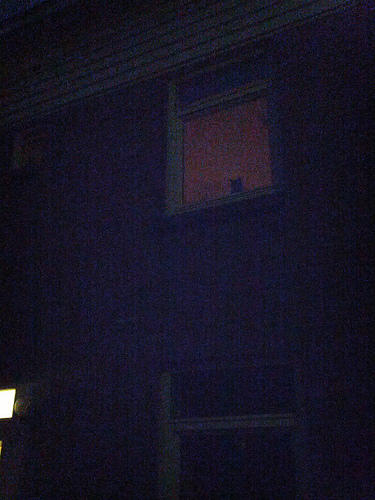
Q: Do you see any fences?
A: No, there are no fences.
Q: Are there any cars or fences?
A: No, there are no fences or cars.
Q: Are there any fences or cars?
A: No, there are no fences or cars.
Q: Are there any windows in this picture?
A: Yes, there is a window.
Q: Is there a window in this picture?
A: Yes, there is a window.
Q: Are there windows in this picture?
A: Yes, there is a window.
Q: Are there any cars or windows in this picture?
A: Yes, there is a window.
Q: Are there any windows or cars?
A: Yes, there is a window.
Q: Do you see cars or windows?
A: Yes, there is a window.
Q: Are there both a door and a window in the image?
A: Yes, there are both a window and a door.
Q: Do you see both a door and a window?
A: Yes, there are both a window and a door.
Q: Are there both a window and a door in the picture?
A: Yes, there are both a window and a door.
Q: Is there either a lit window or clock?
A: Yes, there is a lit window.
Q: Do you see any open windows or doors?
A: Yes, there is an open window.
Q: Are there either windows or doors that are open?
A: Yes, the window is open.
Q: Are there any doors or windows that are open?
A: Yes, the window is open.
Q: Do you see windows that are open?
A: Yes, there is an open window.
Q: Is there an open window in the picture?
A: Yes, there is an open window.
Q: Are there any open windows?
A: Yes, there is an open window.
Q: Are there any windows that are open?
A: Yes, there is a window that is open.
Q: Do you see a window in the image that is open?
A: Yes, there is a window that is open.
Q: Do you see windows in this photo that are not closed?
A: Yes, there is a open window.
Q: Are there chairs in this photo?
A: No, there are no chairs.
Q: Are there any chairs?
A: No, there are no chairs.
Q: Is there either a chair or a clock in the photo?
A: No, there are no chairs or clocks.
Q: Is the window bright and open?
A: Yes, the window is bright and open.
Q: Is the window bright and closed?
A: No, the window is bright but open.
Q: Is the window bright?
A: Yes, the window is bright.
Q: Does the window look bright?
A: Yes, the window is bright.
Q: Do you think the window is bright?
A: Yes, the window is bright.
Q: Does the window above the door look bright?
A: Yes, the window is bright.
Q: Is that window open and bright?
A: Yes, the window is open and bright.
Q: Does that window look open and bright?
A: Yes, the window is open and bright.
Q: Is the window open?
A: Yes, the window is open.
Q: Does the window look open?
A: Yes, the window is open.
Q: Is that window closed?
A: No, the window is open.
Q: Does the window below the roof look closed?
A: No, the window is open.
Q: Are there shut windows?
A: No, there is a window but it is open.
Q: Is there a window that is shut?
A: No, there is a window but it is open.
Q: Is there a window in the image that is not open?
A: No, there is a window but it is open.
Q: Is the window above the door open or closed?
A: The window is open.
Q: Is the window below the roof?
A: Yes, the window is below the roof.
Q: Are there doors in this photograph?
A: Yes, there is a door.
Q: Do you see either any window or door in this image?
A: Yes, there is a door.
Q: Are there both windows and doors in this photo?
A: Yes, there are both a door and a window.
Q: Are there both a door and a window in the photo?
A: Yes, there are both a door and a window.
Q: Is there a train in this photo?
A: No, there are no trains.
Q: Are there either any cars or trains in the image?
A: No, there are no trains or cars.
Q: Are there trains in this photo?
A: No, there are no trains.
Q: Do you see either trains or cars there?
A: No, there are no trains or cars.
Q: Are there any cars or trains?
A: No, there are no trains or cars.